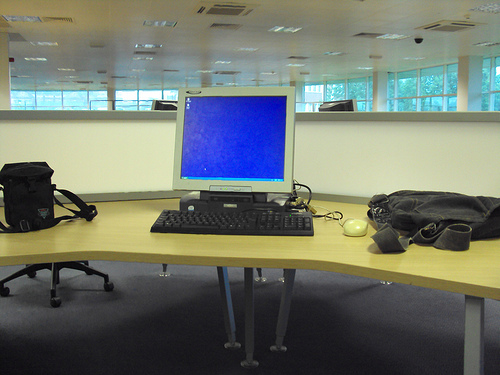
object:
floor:
[0, 266, 499, 375]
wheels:
[0, 266, 115, 308]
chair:
[0, 260, 115, 308]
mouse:
[342, 219, 368, 237]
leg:
[270, 268, 297, 353]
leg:
[240, 267, 260, 369]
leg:
[217, 266, 242, 351]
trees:
[0, 260, 115, 308]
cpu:
[179, 191, 287, 213]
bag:
[0, 161, 98, 234]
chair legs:
[0, 260, 110, 298]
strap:
[0, 188, 98, 233]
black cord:
[291, 183, 344, 220]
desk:
[0, 194, 500, 374]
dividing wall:
[0, 109, 500, 200]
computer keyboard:
[150, 208, 315, 236]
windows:
[385, 61, 458, 113]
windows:
[324, 75, 374, 112]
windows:
[10, 88, 178, 110]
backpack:
[367, 189, 500, 254]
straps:
[370, 222, 474, 254]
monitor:
[172, 86, 296, 194]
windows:
[479, 55, 500, 112]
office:
[0, 0, 500, 375]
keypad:
[282, 214, 311, 230]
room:
[0, 0, 500, 375]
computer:
[172, 86, 297, 213]